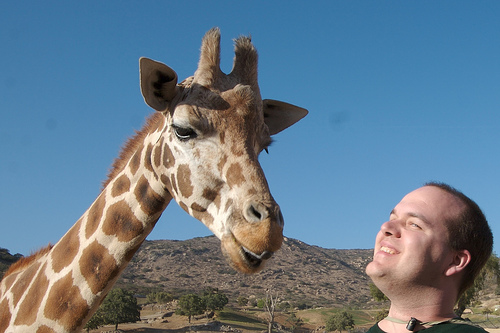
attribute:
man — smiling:
[359, 150, 491, 332]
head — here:
[387, 174, 485, 291]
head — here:
[119, 50, 306, 286]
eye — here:
[158, 108, 205, 151]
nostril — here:
[245, 186, 276, 226]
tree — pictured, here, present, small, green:
[179, 266, 208, 331]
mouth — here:
[373, 241, 403, 259]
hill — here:
[188, 249, 384, 312]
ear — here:
[433, 228, 475, 282]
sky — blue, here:
[303, 19, 500, 165]